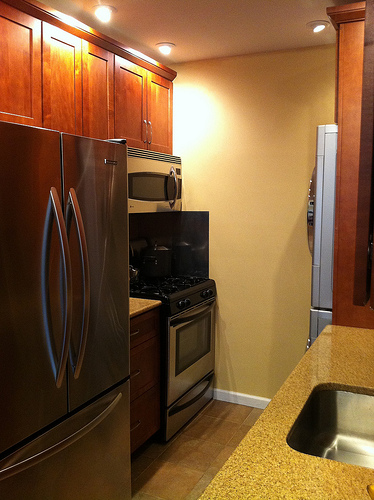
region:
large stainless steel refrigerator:
[0, 108, 162, 498]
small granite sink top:
[185, 315, 373, 497]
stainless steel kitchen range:
[130, 258, 226, 451]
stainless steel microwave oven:
[113, 135, 191, 226]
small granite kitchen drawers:
[103, 283, 184, 469]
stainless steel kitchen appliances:
[2, 102, 345, 498]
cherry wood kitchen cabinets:
[2, 0, 181, 166]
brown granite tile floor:
[115, 376, 279, 498]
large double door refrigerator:
[0, 110, 158, 498]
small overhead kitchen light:
[293, 12, 338, 47]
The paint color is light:
[192, 111, 297, 213]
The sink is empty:
[272, 391, 371, 464]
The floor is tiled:
[159, 405, 256, 497]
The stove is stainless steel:
[143, 278, 268, 467]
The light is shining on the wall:
[164, 79, 236, 182]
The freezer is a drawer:
[11, 395, 128, 496]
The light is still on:
[147, 29, 189, 73]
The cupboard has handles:
[136, 115, 164, 146]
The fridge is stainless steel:
[41, 134, 145, 413]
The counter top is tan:
[248, 455, 310, 497]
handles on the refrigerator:
[40, 181, 97, 395]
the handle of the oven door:
[169, 297, 221, 330]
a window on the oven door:
[170, 307, 215, 376]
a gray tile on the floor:
[201, 393, 256, 426]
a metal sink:
[282, 375, 373, 477]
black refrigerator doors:
[0, 120, 141, 469]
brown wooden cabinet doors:
[0, 1, 47, 128]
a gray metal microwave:
[127, 144, 190, 216]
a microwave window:
[127, 171, 175, 203]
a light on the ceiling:
[156, 40, 174, 59]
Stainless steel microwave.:
[127, 146, 181, 213]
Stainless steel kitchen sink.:
[283, 379, 371, 469]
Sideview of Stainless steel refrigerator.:
[305, 121, 335, 347]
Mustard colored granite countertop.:
[230, 457, 336, 497]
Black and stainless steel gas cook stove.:
[143, 278, 222, 440]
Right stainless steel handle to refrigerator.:
[69, 187, 94, 379]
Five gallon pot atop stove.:
[141, 240, 169, 279]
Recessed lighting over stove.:
[96, 5, 116, 26]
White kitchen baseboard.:
[215, 388, 270, 407]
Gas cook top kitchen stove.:
[136, 270, 213, 298]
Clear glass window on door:
[178, 312, 212, 368]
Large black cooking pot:
[136, 246, 171, 280]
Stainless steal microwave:
[127, 147, 183, 211]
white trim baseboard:
[215, 387, 266, 410]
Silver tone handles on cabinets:
[142, 117, 154, 149]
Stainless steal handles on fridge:
[46, 187, 91, 386]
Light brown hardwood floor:
[188, 419, 222, 471]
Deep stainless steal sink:
[295, 393, 370, 462]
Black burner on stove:
[147, 284, 176, 297]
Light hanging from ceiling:
[153, 35, 180, 56]